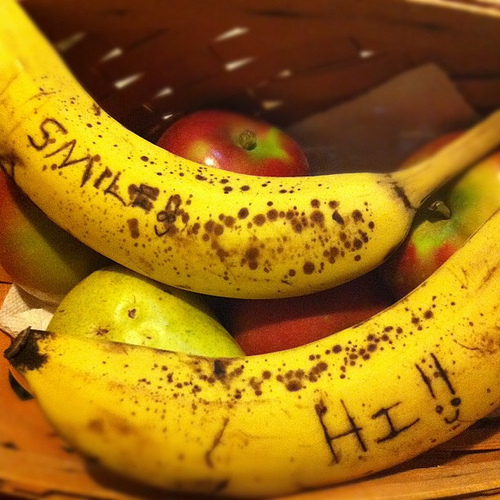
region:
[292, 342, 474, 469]
carving on a banana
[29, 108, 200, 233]
carving on a banan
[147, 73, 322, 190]
a red apple in a box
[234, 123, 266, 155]
stem of an apple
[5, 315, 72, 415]
top of a banana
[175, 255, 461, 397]
spots on a banana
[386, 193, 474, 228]
stem of an apple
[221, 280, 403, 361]
apple in a box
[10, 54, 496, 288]
banana in a box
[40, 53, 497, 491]
fruits in a box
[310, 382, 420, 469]
writing on yellow banana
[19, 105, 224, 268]
writing on yellow banana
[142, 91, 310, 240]
apple behind yellow banana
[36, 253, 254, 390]
pear behind yellow banana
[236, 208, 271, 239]
brown spot on banana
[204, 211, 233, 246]
brown spot on banana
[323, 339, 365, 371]
brown spot on banana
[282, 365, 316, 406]
brown spot on banana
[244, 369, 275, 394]
brown spot on banana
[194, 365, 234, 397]
brown spot on banana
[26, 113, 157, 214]
Smile written on banana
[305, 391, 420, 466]
Hi written on banana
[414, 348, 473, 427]
Exclamation smiling face on banana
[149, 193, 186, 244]
Exclamation smiling face on banana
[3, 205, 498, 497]
Brown and yellow banana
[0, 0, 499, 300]
Brown and yellow banana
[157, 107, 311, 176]
Red and green apple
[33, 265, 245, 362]
Green and brown pear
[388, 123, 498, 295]
Green and red apple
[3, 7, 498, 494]
Basket full of fruits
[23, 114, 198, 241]
words on the banana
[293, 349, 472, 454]
words on a banana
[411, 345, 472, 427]
drawing on the banana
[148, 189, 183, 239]
drawing on the banana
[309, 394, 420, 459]
words written on fruit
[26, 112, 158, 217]
words written on fruit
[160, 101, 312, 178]
apple next to banana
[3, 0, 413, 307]
banana in a basket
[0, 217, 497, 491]
banana in a basket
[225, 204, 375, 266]
spots on fruit